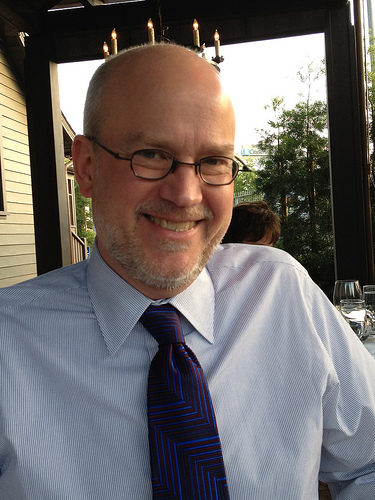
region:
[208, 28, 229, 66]
This is a candle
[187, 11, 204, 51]
This is a candle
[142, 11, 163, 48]
This is a candle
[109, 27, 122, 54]
This is a candle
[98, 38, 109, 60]
This is a candle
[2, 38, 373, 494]
This is a man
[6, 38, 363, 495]
This is a person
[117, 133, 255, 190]
Eyes of a man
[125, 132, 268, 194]
Eyes of a person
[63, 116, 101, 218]
Ear of a man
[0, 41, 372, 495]
Man with glasses and a bald head smiling.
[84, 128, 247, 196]
Small wire framed glasses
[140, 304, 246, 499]
Black tie with red and blue geometric pattern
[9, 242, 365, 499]
Blue and white striped shirt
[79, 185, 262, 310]
Neatly trimmed beard and mustache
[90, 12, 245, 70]
Light fixture consisting of many faux candles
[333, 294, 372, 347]
Water glass on table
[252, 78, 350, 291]
Leafy green tree in background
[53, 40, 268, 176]
Bald head with light hair on sides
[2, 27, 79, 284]
Yellow siding on building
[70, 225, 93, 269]
Wooden railing for outdoor steps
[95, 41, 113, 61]
light on the chandelier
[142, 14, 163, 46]
light on the chandelier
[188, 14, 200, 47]
light on the chandelier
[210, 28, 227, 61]
light on the chandelier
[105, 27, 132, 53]
light on the chandelier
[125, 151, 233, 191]
glasses on the man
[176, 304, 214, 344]
corner of the collar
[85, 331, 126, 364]
corner of the collar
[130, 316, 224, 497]
tie on the man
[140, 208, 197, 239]
smile on the man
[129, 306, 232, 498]
part of a purple and blue tie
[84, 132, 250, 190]
a man's eyeglasses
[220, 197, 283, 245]
a woman's brown hair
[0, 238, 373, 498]
a man's long sleeve shirt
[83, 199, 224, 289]
a man's gray beard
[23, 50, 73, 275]
a tall wooden pole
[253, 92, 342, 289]
a tall green tree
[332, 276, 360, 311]
a large glass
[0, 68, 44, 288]
siding of a house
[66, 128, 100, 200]
the ear of a man